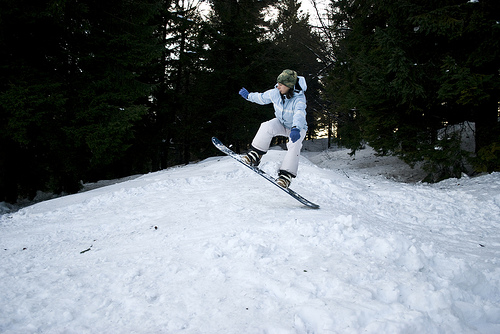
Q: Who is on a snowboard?
A: A woman.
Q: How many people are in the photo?
A: One.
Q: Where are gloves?
A: On woman's hands.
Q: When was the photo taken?
A: Daytime.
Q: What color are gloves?
A: Blue.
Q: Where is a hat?
A: On a woman's head.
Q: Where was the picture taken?
A: On snow.